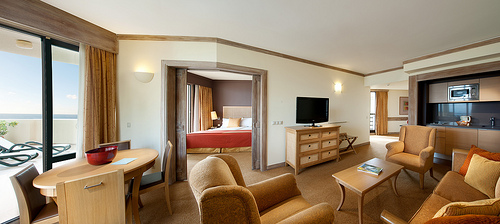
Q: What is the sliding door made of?
A: Glass.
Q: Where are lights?
A: On the wall.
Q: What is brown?
A: Couches.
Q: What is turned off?
A: TV.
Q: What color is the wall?
A: White.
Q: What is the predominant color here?
A: A buttery beige color.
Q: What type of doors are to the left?
A: Sliding glass doors.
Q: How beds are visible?
A: One.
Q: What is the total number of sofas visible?
A: One.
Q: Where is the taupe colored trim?
A: Around the doorway to the bedroom.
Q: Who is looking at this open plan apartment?
A: The photographer.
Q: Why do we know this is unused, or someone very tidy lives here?
A: Because it is immaculate.